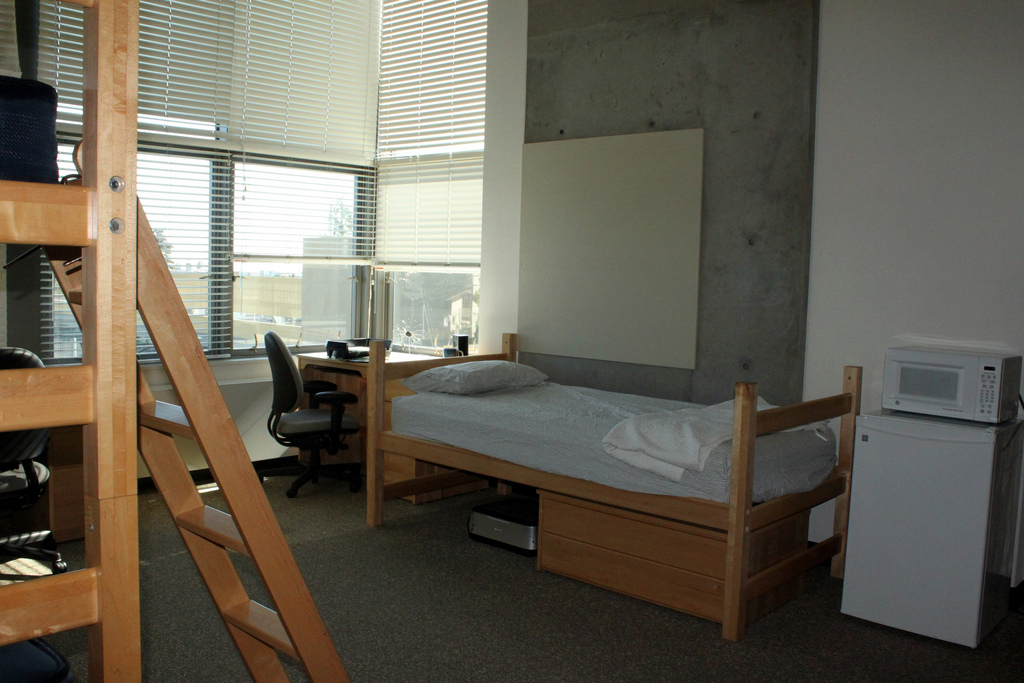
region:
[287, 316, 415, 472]
desk in the corner of the room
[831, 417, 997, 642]
small white fridge against the wall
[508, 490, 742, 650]
two wooden drawers under the bed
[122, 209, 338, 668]
wooden ladder to top bunk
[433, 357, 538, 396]
white pillow in the bed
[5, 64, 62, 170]
mattress on top bunk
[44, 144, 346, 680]
a short wooden staircase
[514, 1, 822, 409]
large light panel affixed to concrete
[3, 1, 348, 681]
ladder leads to edge of bunk bed railing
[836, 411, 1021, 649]
a white mini fridge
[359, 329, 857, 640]
folded sheet on foot of bed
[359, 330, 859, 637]
black and silver box-like object beneath bed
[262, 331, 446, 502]
grey and black office chair close to a desk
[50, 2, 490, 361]
six windows in two rows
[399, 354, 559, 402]
a white pillow on a bed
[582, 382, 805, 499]
a white blanket on a bed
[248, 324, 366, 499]
a black and grey chair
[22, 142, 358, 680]
a small set of stairs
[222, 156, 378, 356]
a small black window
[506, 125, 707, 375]
a white patch of material on a wall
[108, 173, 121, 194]
a metal bolt on a bed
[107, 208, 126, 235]
a metal bolt on a bed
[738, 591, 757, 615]
leg of the bed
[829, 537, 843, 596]
leg of the bed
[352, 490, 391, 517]
leg of the bed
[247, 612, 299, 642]
wood on the ladder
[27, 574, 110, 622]
wood on the ladder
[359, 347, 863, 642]
wooden bed in dorm room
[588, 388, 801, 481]
white blanket draped over foot of bed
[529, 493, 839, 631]
drawers under wooden bed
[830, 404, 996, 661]
small white dorm refrigerator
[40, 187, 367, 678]
wooden steps to bunk bed in dorm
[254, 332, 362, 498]
captain's chair for computer desk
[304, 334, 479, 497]
wooden computer desk for studying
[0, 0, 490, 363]
venetian blinds protecting room from sun rays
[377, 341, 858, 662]
student bed with built in drawers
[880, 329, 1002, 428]
small white microwave oven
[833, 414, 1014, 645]
small white dorm fridge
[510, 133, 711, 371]
wipe board mounted on wall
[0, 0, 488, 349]
tall wide windows with blinds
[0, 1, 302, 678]
loft or bunk style bed with ladder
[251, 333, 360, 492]
rolling desk chair with arms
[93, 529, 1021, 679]
flat grey carpeted area